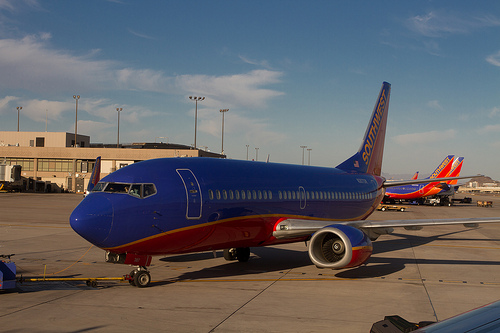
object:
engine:
[306, 224, 374, 269]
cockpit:
[64, 176, 164, 239]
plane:
[67, 80, 499, 290]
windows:
[102, 182, 131, 196]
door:
[174, 167, 205, 219]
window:
[207, 191, 215, 201]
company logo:
[349, 159, 360, 170]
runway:
[0, 191, 498, 331]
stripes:
[4, 272, 493, 291]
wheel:
[129, 269, 153, 289]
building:
[0, 129, 223, 194]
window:
[66, 161, 75, 171]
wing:
[270, 216, 500, 238]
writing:
[359, 87, 388, 165]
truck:
[0, 160, 22, 191]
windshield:
[101, 182, 129, 192]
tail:
[336, 81, 393, 177]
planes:
[377, 156, 467, 208]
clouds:
[0, 30, 287, 144]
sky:
[0, 1, 499, 180]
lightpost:
[186, 96, 204, 150]